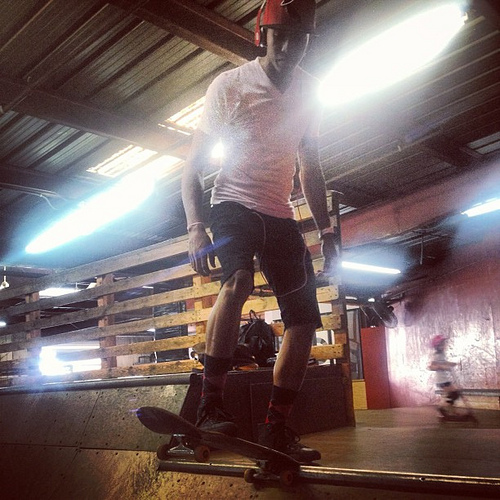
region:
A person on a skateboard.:
[131, 3, 346, 488]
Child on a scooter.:
[425, 332, 485, 426]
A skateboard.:
[131, 403, 304, 489]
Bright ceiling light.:
[25, 165, 156, 260]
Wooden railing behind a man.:
[1, 185, 342, 381]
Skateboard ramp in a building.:
[5, 370, 498, 495]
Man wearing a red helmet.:
[251, 0, 316, 80]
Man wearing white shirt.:
[180, 0, 325, 216]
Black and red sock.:
[261, 382, 298, 431]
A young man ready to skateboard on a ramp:
[130, 2, 365, 482]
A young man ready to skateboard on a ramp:
[127, 5, 344, 481]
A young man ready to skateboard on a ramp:
[126, 5, 349, 480]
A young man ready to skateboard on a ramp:
[123, 2, 353, 485]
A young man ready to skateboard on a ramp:
[130, 5, 350, 476]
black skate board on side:
[127, 392, 303, 479]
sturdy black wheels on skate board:
[144, 427, 214, 469]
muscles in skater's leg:
[169, 299, 261, 364]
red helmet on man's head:
[236, 2, 341, 41]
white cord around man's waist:
[241, 194, 278, 277]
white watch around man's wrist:
[307, 219, 350, 240]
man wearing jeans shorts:
[208, 196, 345, 327]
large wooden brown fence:
[46, 263, 187, 378]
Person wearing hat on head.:
[264, 13, 311, 30]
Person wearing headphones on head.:
[239, 30, 281, 53]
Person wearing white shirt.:
[219, 93, 287, 170]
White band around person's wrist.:
[176, 212, 213, 239]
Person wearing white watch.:
[316, 223, 353, 241]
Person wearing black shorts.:
[211, 211, 295, 276]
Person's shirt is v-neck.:
[259, 67, 324, 129]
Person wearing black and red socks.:
[178, 358, 295, 442]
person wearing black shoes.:
[196, 410, 311, 474]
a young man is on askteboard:
[136, 44, 296, 489]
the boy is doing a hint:
[164, 96, 273, 388]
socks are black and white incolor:
[193, 350, 310, 433]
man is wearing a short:
[186, 84, 329, 318]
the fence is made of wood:
[101, 258, 189, 370]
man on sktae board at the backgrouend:
[413, 325, 491, 446]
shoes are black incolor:
[269, 416, 324, 487]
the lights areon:
[346, 248, 418, 314]